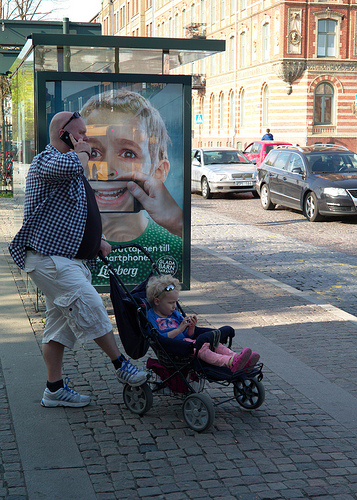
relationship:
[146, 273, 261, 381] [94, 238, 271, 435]
baby in stroller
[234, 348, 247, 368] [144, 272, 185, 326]
shoe on kid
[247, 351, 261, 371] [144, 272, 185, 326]
shoe on kid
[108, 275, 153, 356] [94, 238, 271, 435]
bag on stroller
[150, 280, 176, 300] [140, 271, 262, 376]
sunglasses on kid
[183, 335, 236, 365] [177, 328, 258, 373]
pants on legs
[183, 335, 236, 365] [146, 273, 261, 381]
pants on baby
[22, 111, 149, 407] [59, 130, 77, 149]
man talking on cell phone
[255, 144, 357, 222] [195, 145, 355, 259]
car driving on road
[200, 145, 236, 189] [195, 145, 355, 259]
car driving on road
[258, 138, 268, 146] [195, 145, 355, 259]
car driving on road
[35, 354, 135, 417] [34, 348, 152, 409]
socks sticking out of shoes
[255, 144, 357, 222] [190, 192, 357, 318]
car driving on road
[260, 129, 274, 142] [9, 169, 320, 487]
person walking on sidewalk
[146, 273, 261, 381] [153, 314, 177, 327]
baby wearing shirt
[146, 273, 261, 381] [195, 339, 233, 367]
baby wearing pants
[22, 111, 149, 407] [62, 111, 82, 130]
man wearing glasses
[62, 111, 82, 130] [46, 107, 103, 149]
glasses on head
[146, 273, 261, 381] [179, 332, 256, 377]
baby wearing pants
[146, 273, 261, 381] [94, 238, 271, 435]
baby on stroller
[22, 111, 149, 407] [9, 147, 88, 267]
man wearing shirt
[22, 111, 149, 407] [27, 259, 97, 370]
man wearing khaki pants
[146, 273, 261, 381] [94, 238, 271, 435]
baby sitting in stroller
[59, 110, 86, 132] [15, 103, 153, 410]
glasses on man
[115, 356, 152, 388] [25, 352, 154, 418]
shoes on feet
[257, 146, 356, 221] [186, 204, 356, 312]
car in street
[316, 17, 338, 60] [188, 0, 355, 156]
window of a building